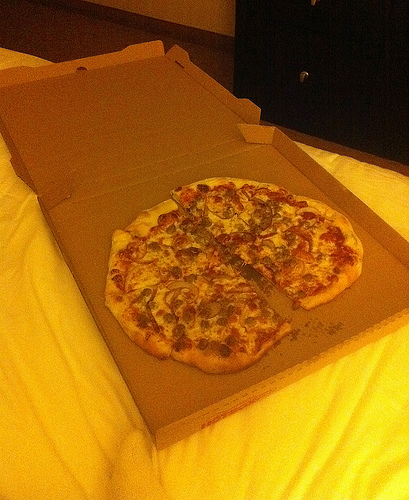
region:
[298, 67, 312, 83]
Round knob on front of black furniture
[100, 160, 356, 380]
Round pizza in cardboard box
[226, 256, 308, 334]
Space between two halves of pizza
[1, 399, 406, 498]
Yellow surface under pizza box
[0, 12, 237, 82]
Dark colored flooring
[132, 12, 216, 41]
Base trim on bottom of wall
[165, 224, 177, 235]
Piece of sausage on pizza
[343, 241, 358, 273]
Pizza sauce on top of pizza crust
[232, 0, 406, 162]
Black piece of furniture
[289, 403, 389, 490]
Creases in yellow surface under pizza box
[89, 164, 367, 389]
pizza in a box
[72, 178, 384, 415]
hot pizza in a box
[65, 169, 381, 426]
good pizza in a box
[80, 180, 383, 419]
delicious pizza in a box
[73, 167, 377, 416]
flavorful pizza in a box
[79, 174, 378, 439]
tasty pizza in a box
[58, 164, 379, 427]
some great pizza in a box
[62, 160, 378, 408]
well seasoned pizza in a box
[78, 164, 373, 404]
chunky pizza in a box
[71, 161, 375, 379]
chunky cheesy pizza in a box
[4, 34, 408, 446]
cardboard box pizza is in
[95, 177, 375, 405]
pizza cut in half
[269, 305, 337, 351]
grease stains on cardboard box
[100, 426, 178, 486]
foot with sock on it next to box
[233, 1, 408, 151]
black dresser against wall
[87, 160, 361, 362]
pizza sitting in box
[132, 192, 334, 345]
cheese on top of pizza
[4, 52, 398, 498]
bed pizza box is on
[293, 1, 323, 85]
silver knobs on black dresser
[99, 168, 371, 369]
crust of the pizza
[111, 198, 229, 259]
slice of pizza in a box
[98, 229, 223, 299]
slice of pizza in a box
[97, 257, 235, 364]
slice of pizza in a box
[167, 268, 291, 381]
slice of pizza in a box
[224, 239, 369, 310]
slice of pizza in a box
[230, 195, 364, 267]
slice of pizza in a box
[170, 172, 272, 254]
slice of pizza in a box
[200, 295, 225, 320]
mushroom on a pizza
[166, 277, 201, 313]
mushroom on a pizza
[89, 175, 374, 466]
This is a large pizza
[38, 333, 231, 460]
This is a cardboard box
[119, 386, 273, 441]
The box is brown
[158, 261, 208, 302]
These are mushrooms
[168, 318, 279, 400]
This is a crust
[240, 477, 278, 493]
This is a blanket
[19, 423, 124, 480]
The cloth is yellow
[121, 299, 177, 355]
These are burnt spots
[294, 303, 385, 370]
This is a little grease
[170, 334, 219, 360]
The crust is thin